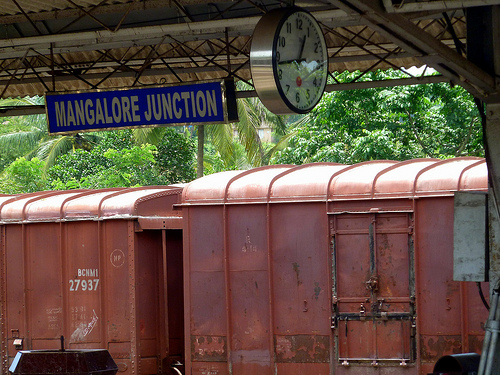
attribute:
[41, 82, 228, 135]
sign — blue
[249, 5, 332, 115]
clock — overhead, large, silver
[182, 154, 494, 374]
train car — rusted, red, old, red-orange, faded, rundown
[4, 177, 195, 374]
train car — red-orange, rusted, red, old, faded, rundown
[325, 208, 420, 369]
door — locked, rusted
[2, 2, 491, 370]
train station — old, small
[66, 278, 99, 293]
number 27937 — white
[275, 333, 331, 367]
paint — chipping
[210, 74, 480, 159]
leaves — green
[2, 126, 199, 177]
leaves — green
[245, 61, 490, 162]
tree — green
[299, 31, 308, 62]
hand — black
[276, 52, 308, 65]
hand — black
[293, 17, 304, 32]
number 12 — black